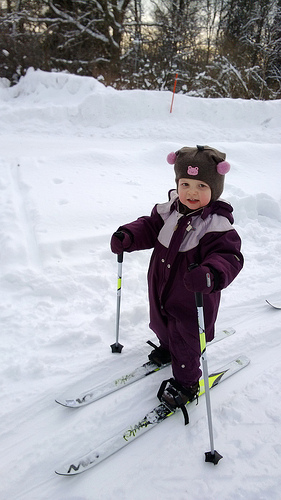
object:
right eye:
[181, 181, 190, 187]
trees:
[267, 0, 280, 95]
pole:
[115, 252, 123, 347]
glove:
[183, 264, 216, 295]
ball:
[216, 160, 231, 177]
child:
[108, 143, 246, 413]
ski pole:
[194, 291, 215, 456]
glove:
[109, 229, 132, 257]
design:
[186, 165, 199, 177]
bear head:
[187, 165, 200, 176]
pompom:
[216, 160, 231, 177]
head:
[174, 144, 227, 211]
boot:
[160, 377, 200, 409]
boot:
[147, 341, 173, 368]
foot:
[150, 342, 172, 366]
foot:
[161, 375, 201, 409]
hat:
[165, 143, 232, 207]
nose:
[187, 188, 198, 196]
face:
[177, 177, 213, 211]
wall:
[135, 59, 164, 88]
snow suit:
[109, 187, 245, 386]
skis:
[53, 352, 252, 478]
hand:
[182, 265, 211, 294]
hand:
[110, 230, 131, 256]